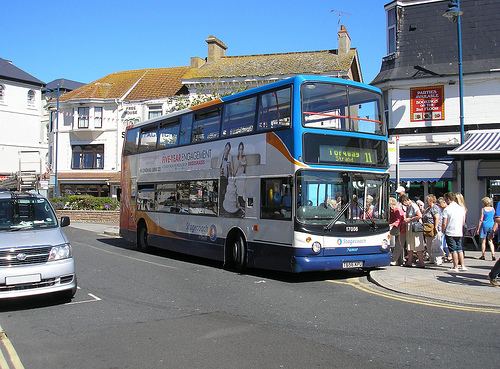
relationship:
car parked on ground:
[0, 190, 77, 299] [0, 209, 500, 369]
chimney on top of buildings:
[195, 27, 245, 70] [0, 25, 365, 203]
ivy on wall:
[175, 71, 271, 102] [188, 86, 235, 104]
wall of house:
[188, 86, 235, 104] [192, 25, 373, 104]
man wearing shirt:
[442, 192, 467, 272] [445, 201, 466, 238]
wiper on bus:
[325, 197, 354, 229] [119, 71, 394, 278]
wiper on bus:
[356, 202, 378, 226] [119, 71, 394, 278]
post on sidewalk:
[450, 5, 467, 150] [390, 247, 499, 303]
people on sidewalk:
[389, 191, 469, 273] [386, 249, 497, 302]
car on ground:
[0, 190, 77, 299] [0, 209, 500, 369]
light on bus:
[307, 241, 327, 252] [119, 71, 394, 278]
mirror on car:
[58, 211, 71, 233] [0, 190, 77, 299]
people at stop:
[389, 178, 466, 272] [390, 233, 498, 263]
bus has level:
[119, 71, 394, 278] [113, 83, 410, 162]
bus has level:
[119, 71, 394, 278] [105, 168, 415, 285]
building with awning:
[370, 0, 499, 237] [447, 129, 497, 156]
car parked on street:
[1, 188, 77, 317] [98, 275, 247, 366]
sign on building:
[407, 80, 447, 123] [378, 10, 490, 253]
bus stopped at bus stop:
[119, 71, 394, 278] [365, 230, 499, 284]